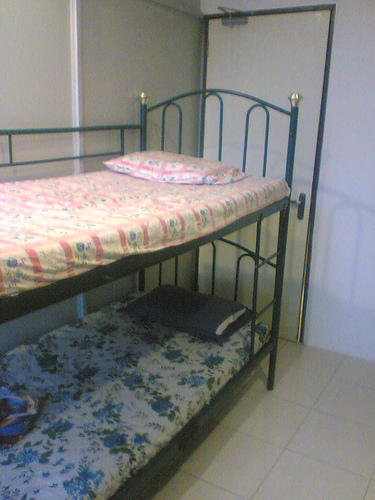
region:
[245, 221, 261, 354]
green metal railing on bed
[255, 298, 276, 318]
green metal railing on bed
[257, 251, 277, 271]
green metal railing on bed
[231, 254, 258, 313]
green metal railing on bed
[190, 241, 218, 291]
green metal railing on bed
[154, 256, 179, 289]
green metal railing on bed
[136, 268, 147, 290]
green metal railing on bed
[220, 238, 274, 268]
green metal railing on bed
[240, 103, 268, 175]
green metal railing on bed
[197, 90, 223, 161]
green metal railing on bed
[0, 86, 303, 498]
a blue and gold bunk bed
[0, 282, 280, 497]
a blue and green flower pattern sheet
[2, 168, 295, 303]
a red, blue, white, and green flower pattern sheet.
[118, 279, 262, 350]
a pillow with a blue pillow case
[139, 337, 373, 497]
white tiles on the floor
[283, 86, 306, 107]
a gold top on bunkbed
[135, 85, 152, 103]
a gold top on a bunk bed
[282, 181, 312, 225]
a black metal door handle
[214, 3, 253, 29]
a door swing spring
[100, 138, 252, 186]
a pillow on the top bunk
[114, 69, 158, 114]
golden orante bed topping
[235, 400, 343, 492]
a clean tile flooring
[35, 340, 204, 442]
a bed with floral print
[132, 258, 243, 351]
a dark blue pillow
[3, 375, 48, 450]
some kind of clothing item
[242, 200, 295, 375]
a small step ladder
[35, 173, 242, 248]
a pink bed patterning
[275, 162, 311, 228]
a handle of a door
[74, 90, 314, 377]
a large bunk bed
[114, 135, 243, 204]
a pink and white pillow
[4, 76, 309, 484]
A metal frame bunk bed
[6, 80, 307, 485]
A metal frame bunk bed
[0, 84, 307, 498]
dark blue colored metal bunk beds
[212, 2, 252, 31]
metal self closing door hinge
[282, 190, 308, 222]
silver door lever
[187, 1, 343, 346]
cream colored bedroom door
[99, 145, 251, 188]
bed pillow with pillowcase on it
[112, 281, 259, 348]
bed pillow with blue pillow case on it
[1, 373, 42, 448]
blanket bunched up at bottom of bed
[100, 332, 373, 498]
off white colored linoleum tiled floor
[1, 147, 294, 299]
white, pink and blue sheets and pillow case set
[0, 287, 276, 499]
flower patterned fitted sheet on twin bed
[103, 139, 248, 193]
Pillow on a bed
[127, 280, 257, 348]
Pillow on a bed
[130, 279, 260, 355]
Blue pillow on a bed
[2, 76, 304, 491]
black iron bunk bed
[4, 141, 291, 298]
floral sheets on black iron bunk bed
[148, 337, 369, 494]
white tiled floor in bedroom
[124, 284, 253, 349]
blue bed pillow on bottom bunk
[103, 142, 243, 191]
pink and white floral pillow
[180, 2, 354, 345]
very tall white door in bedroom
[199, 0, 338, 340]
very tall white door outlined in black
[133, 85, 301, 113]
brass knobs on top of bunk bed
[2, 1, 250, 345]
white walls in bed room